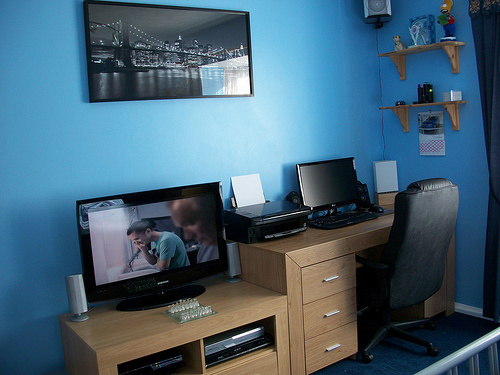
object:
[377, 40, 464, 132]
shelves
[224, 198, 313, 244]
printer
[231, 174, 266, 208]
paper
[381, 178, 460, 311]
leather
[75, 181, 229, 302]
tv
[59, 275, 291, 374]
table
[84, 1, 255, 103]
photograph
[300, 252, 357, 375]
drawers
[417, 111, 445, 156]
calendar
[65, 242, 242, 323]
speakers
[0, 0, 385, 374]
walls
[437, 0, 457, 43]
figurine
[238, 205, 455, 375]
desk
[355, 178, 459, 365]
chair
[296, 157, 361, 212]
cpu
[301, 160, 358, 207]
monitor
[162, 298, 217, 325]
set